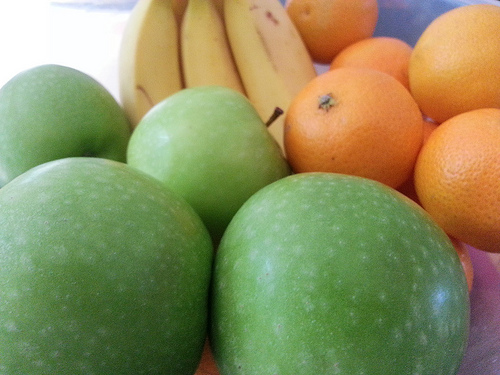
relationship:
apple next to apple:
[210, 171, 472, 374] [127, 85, 297, 235]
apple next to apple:
[0, 157, 216, 374] [210, 171, 472, 374]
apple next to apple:
[2, 63, 130, 187] [127, 85, 297, 235]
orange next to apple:
[282, 66, 422, 189] [127, 85, 297, 235]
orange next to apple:
[413, 106, 499, 253] [210, 171, 472, 374]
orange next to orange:
[407, 5, 497, 123] [282, 66, 422, 189]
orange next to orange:
[329, 35, 412, 92] [407, 5, 497, 123]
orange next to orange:
[285, 0, 380, 66] [329, 35, 412, 92]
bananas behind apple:
[118, 1, 319, 159] [127, 85, 297, 235]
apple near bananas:
[127, 85, 297, 235] [118, 1, 319, 159]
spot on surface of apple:
[294, 244, 302, 256] [210, 171, 472, 374]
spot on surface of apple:
[303, 296, 314, 313] [210, 171, 472, 374]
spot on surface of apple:
[333, 222, 342, 233] [210, 171, 472, 374]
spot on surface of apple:
[419, 244, 430, 258] [210, 171, 472, 374]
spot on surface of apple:
[402, 319, 413, 332] [210, 171, 472, 374]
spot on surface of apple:
[37, 190, 50, 202] [0, 157, 216, 374]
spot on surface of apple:
[119, 192, 131, 201] [0, 157, 216, 374]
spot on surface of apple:
[73, 189, 83, 197] [0, 157, 216, 374]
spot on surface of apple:
[15, 338, 41, 357] [0, 157, 216, 374]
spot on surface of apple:
[95, 327, 108, 338] [0, 157, 216, 374]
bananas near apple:
[118, 1, 319, 159] [2, 63, 130, 187]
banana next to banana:
[180, 0, 246, 99] [222, 0, 319, 161]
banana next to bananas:
[180, 0, 246, 99] [118, 0, 186, 137]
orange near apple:
[282, 66, 422, 189] [127, 85, 297, 235]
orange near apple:
[413, 106, 499, 253] [210, 171, 472, 374]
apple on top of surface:
[0, 157, 216, 374] [1, 0, 499, 374]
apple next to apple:
[127, 85, 297, 235] [0, 157, 216, 374]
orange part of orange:
[282, 66, 422, 189] [407, 5, 497, 123]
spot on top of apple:
[294, 244, 302, 256] [210, 171, 472, 374]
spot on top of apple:
[333, 222, 342, 233] [210, 171, 472, 374]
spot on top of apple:
[299, 202, 310, 212] [210, 171, 472, 374]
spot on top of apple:
[379, 291, 388, 304] [210, 171, 472, 374]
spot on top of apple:
[378, 211, 389, 228] [210, 171, 472, 374]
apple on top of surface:
[2, 63, 130, 187] [1, 0, 499, 374]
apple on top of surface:
[210, 171, 472, 374] [1, 0, 499, 374]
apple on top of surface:
[127, 85, 297, 235] [1, 0, 499, 374]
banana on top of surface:
[180, 0, 246, 99] [1, 0, 499, 374]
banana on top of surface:
[222, 0, 319, 161] [1, 0, 499, 374]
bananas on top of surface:
[118, 0, 186, 137] [1, 0, 499, 374]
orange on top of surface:
[329, 35, 412, 92] [1, 0, 499, 374]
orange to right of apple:
[282, 66, 422, 189] [127, 85, 297, 235]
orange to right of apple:
[413, 106, 499, 253] [210, 171, 472, 374]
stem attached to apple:
[264, 108, 285, 132] [127, 85, 297, 235]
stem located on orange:
[318, 92, 338, 112] [282, 66, 422, 189]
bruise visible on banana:
[265, 9, 282, 27] [222, 0, 319, 161]